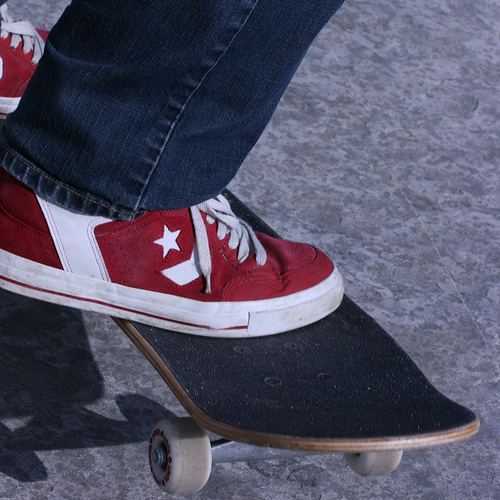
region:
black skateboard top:
[277, 396, 447, 436]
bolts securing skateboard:
[230, 341, 338, 386]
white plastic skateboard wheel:
[133, 413, 230, 493]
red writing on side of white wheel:
[141, 428, 172, 487]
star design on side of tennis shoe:
[149, 219, 191, 260]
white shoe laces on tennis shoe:
[186, 194, 271, 302]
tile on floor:
[346, 111, 467, 273]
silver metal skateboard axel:
[213, 436, 306, 468]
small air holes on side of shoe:
[106, 231, 138, 283]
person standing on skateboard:
[1, 134, 433, 471]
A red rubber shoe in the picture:
[0, 122, 358, 343]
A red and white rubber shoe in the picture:
[2, 139, 390, 344]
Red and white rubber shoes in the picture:
[1, 2, 378, 365]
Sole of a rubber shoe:
[1, 244, 356, 345]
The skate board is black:
[107, 314, 496, 484]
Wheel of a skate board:
[149, 406, 279, 490]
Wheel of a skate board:
[331, 441, 405, 487]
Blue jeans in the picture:
[1, 5, 264, 245]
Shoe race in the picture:
[181, 180, 275, 297]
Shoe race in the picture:
[1, 0, 49, 67]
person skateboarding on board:
[0, 10, 453, 401]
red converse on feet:
[0, 148, 350, 378]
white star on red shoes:
[138, 214, 190, 277]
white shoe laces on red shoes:
[173, 199, 258, 310]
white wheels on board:
[153, 402, 233, 497]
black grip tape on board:
[196, 320, 396, 442]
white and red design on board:
[23, 177, 155, 327]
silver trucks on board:
[236, 439, 303, 476]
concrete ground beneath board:
[234, 139, 450, 494]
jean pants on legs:
[40, 8, 236, 255]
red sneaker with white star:
[0, 152, 374, 333]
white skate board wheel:
[128, 393, 243, 498]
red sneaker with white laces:
[103, 166, 338, 340]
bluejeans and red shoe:
[2, 16, 357, 336]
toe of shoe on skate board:
[46, 218, 498, 484]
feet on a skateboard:
[2, 18, 377, 423]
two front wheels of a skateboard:
[116, 354, 491, 497]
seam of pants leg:
[114, 6, 269, 219]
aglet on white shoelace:
[195, 258, 218, 295]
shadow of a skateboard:
[1, 294, 183, 496]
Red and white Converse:
[10, 104, 387, 336]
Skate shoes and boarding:
[6, 150, 499, 467]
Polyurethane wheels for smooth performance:
[117, 376, 231, 498]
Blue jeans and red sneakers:
[15, 116, 367, 361]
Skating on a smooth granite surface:
[26, 219, 499, 491]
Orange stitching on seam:
[4, 141, 125, 220]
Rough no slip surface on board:
[138, 330, 493, 456]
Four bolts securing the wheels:
[223, 334, 346, 406]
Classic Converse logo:
[98, 204, 245, 297]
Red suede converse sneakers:
[8, 134, 373, 349]